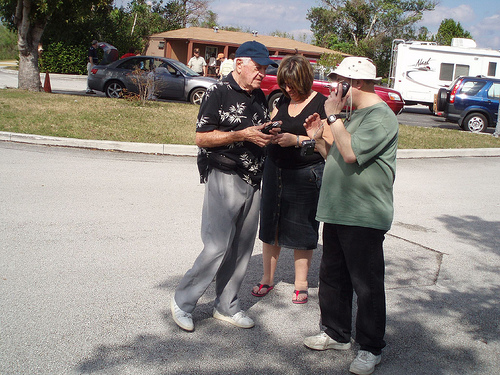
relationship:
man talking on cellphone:
[302, 56, 399, 374] [335, 78, 352, 100]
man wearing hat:
[170, 39, 283, 329] [234, 38, 279, 70]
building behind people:
[140, 25, 356, 82] [188, 45, 235, 81]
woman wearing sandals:
[249, 53, 328, 303] [250, 280, 309, 306]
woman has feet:
[249, 53, 328, 303] [250, 277, 309, 301]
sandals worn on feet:
[250, 280, 309, 306] [250, 277, 309, 301]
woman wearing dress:
[249, 53, 328, 303] [256, 88, 326, 248]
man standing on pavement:
[302, 56, 399, 374] [1, 139, 499, 374]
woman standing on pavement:
[249, 53, 328, 303] [1, 139, 499, 374]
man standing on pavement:
[170, 39, 283, 329] [1, 139, 499, 374]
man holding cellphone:
[302, 56, 399, 374] [335, 78, 352, 100]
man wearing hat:
[302, 56, 399, 374] [326, 54, 381, 83]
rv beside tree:
[386, 35, 498, 111] [321, 38, 366, 73]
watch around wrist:
[327, 112, 339, 125] [326, 112, 340, 123]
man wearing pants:
[302, 56, 399, 374] [318, 223, 387, 356]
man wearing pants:
[170, 39, 283, 329] [173, 167, 261, 317]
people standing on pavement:
[188, 45, 235, 81] [2, 69, 499, 133]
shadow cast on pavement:
[76, 210, 497, 372] [1, 139, 499, 374]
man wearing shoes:
[302, 56, 399, 374] [302, 329, 383, 374]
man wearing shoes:
[170, 39, 283, 329] [170, 295, 257, 332]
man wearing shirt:
[302, 56, 399, 374] [314, 100, 399, 232]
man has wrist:
[302, 56, 399, 374] [326, 112, 340, 123]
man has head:
[302, 56, 399, 374] [327, 54, 383, 105]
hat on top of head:
[326, 54, 381, 83] [327, 54, 383, 105]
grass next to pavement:
[0, 85, 499, 148] [1, 139, 499, 374]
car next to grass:
[86, 54, 220, 104] [0, 85, 499, 148]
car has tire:
[86, 54, 220, 104] [103, 78, 126, 98]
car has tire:
[86, 54, 220, 104] [187, 87, 209, 106]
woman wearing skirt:
[249, 53, 328, 303] [257, 155, 323, 250]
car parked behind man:
[86, 54, 220, 104] [302, 56, 399, 374]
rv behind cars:
[386, 35, 498, 111] [249, 55, 499, 133]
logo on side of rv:
[402, 53, 438, 91] [386, 35, 498, 111]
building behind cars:
[140, 25, 356, 82] [249, 55, 499, 133]